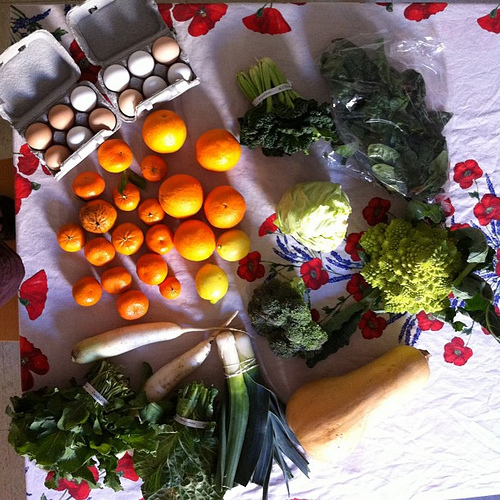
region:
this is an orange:
[166, 182, 195, 209]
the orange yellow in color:
[174, 182, 191, 199]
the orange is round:
[161, 180, 203, 210]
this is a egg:
[73, 87, 92, 104]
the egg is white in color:
[73, 89, 82, 99]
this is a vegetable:
[165, 426, 209, 496]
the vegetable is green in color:
[172, 453, 195, 472]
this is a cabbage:
[295, 187, 332, 233]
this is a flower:
[246, 10, 291, 33]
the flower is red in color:
[273, 17, 283, 25]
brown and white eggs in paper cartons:
[6, 10, 192, 174]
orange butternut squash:
[288, 346, 432, 451]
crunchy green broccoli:
[241, 272, 326, 358]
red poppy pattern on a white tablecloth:
[16, 255, 51, 394]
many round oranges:
[57, 116, 257, 319]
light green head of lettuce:
[271, 176, 351, 250]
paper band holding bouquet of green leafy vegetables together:
[76, 380, 115, 413]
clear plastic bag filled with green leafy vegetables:
[319, 32, 454, 198]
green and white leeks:
[212, 327, 299, 499]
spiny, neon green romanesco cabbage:
[358, 216, 463, 316]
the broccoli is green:
[245, 277, 332, 356]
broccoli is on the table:
[242, 267, 336, 362]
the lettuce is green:
[270, 180, 350, 257]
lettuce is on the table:
[264, 182, 361, 260]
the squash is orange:
[276, 346, 439, 454]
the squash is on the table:
[277, 342, 434, 459]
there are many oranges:
[43, 115, 259, 320]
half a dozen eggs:
[1, 26, 117, 177]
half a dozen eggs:
[65, 0, 200, 115]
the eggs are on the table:
[0, 1, 199, 178]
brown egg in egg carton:
[26, 126, 54, 146]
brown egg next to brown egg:
[27, 120, 69, 167]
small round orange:
[70, 278, 102, 302]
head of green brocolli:
[247, 276, 332, 352]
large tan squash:
[282, 343, 436, 457]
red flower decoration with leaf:
[443, 316, 474, 370]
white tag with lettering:
[249, 83, 289, 106]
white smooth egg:
[104, 66, 131, 88]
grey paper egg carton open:
[0, 31, 117, 171]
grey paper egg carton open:
[65, 2, 200, 109]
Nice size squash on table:
[269, 349, 440, 460]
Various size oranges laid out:
[62, 120, 255, 304]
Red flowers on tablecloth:
[426, 307, 473, 367]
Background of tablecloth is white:
[405, 384, 498, 478]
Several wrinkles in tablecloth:
[371, 410, 465, 497]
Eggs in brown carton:
[47, 57, 197, 109]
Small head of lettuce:
[262, 166, 354, 263]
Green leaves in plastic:
[309, 33, 442, 203]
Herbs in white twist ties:
[43, 382, 226, 469]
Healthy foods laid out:
[0, 42, 499, 478]